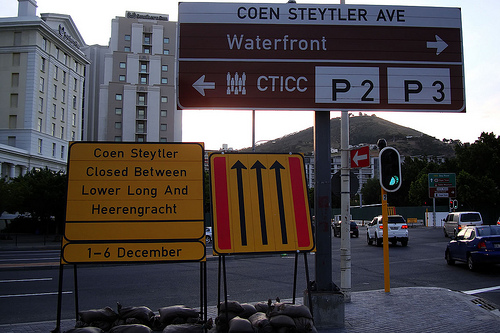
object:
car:
[445, 224, 500, 271]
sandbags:
[69, 296, 318, 332]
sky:
[1, 0, 499, 150]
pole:
[378, 185, 392, 291]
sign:
[208, 150, 318, 255]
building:
[0, 0, 182, 230]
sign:
[348, 145, 371, 167]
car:
[365, 214, 410, 246]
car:
[329, 215, 358, 236]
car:
[441, 209, 483, 237]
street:
[0, 220, 499, 325]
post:
[217, 252, 317, 328]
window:
[123, 34, 130, 41]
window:
[123, 45, 132, 53]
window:
[143, 35, 151, 44]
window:
[142, 47, 151, 54]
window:
[163, 36, 170, 44]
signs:
[218, 155, 304, 249]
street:
[113, 270, 182, 298]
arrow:
[350, 142, 378, 177]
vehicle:
[366, 215, 408, 246]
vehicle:
[332, 221, 359, 239]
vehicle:
[444, 210, 481, 236]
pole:
[296, 99, 340, 328]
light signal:
[373, 145, 401, 294]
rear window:
[458, 213, 481, 222]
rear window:
[379, 215, 404, 222]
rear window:
[476, 225, 498, 238]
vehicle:
[445, 221, 499, 272]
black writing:
[91, 142, 184, 161]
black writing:
[80, 164, 190, 180]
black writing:
[78, 183, 192, 196]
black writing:
[88, 202, 180, 214]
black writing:
[83, 243, 185, 260]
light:
[401, 222, 408, 234]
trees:
[453, 135, 496, 221]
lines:
[0, 288, 63, 294]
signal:
[366, 140, 403, 205]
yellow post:
[68, 141, 310, 259]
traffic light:
[377, 147, 402, 194]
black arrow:
[265, 153, 293, 243]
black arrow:
[250, 155, 270, 246]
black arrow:
[227, 155, 252, 246]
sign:
[57, 139, 207, 264]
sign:
[172, 2, 469, 114]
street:
[384, 237, 490, 286]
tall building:
[2, 0, 182, 171]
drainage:
[455, 281, 484, 322]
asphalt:
[425, 280, 477, 296]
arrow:
[414, 32, 455, 65]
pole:
[334, 107, 354, 296]